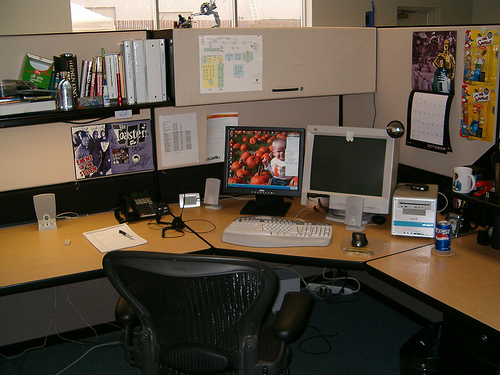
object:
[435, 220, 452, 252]
soda can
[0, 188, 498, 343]
desk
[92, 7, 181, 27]
window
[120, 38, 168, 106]
binders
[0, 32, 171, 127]
shelf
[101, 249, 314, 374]
chair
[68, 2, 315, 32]
window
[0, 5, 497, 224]
background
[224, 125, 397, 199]
monitors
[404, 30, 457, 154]
calendar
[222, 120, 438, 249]
computer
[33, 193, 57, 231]
speaker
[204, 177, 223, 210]
speaker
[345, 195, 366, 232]
speaker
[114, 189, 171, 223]
phone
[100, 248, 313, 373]
office chair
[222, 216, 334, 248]
keyboard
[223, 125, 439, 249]
computer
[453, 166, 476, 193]
mug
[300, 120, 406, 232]
computer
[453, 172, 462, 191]
picture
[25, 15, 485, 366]
office cubical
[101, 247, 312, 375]
blue sky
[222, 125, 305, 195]
monitor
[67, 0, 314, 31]
outside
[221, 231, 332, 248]
wrist rest